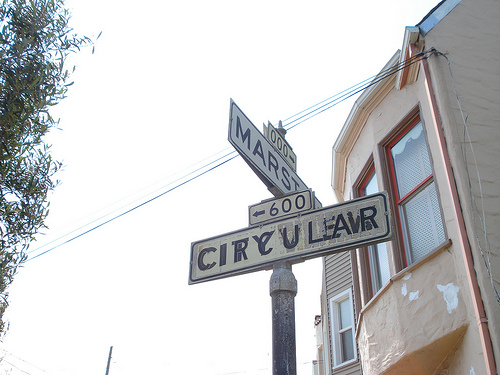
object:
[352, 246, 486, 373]
wall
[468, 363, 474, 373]
chipped painting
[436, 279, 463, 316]
chipped painting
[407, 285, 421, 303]
chipped painting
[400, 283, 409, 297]
chipped painting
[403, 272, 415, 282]
chipped painting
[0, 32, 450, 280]
wire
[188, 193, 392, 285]
sign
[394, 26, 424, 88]
gutter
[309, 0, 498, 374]
building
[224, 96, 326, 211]
sign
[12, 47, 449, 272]
telephone wires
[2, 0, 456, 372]
cloudless sky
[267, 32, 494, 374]
house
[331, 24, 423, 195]
roof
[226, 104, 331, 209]
signs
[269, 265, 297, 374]
pole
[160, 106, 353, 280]
sign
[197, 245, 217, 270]
black letters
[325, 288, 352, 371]
window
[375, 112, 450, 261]
window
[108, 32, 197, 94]
sky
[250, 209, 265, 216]
arrow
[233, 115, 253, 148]
letters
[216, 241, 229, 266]
letters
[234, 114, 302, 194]
name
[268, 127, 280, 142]
number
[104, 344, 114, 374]
pole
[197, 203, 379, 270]
name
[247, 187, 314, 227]
sign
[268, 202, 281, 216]
number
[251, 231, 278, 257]
writing